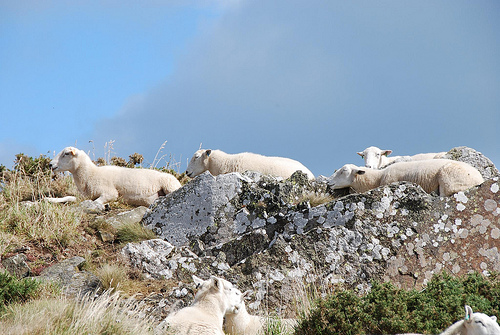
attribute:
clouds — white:
[167, 3, 477, 139]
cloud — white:
[53, 1, 499, 177]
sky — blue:
[0, 0, 498, 173]